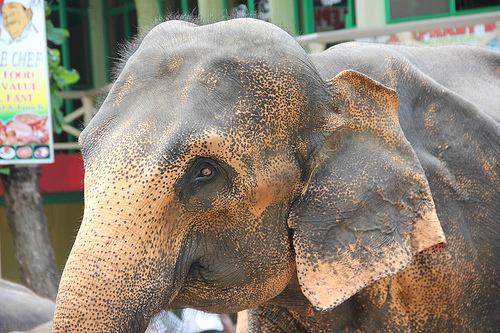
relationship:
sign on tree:
[0, 4, 57, 166] [2, 159, 64, 304]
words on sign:
[2, 38, 42, 106] [0, 4, 57, 166]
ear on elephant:
[287, 67, 448, 313] [55, 12, 498, 329]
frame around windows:
[301, 2, 317, 34] [60, 21, 457, 68]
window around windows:
[383, 0, 456, 23] [60, 21, 457, 68]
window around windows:
[91, 16, 146, 85] [60, 21, 457, 68]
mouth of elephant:
[167, 241, 232, 311] [55, 12, 498, 329]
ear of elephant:
[287, 67, 448, 313] [55, 12, 498, 329]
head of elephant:
[78, 18, 305, 306] [55, 12, 498, 329]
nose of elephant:
[48, 212, 195, 330] [55, 12, 498, 329]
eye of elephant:
[185, 158, 219, 186] [55, 12, 498, 329]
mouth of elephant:
[75, 159, 311, 331] [56, 41, 488, 289]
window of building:
[91, 16, 146, 85] [65, 15, 371, 97]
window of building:
[91, 16, 146, 85] [52, 1, 497, 51]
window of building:
[383, 0, 456, 23] [43, 0, 498, 192]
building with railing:
[5, 3, 499, 291] [44, 85, 133, 151]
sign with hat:
[0, 4, 57, 166] [3, 1, 34, 8]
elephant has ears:
[55, 12, 498, 329] [285, 68, 447, 313]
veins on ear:
[302, 183, 428, 256] [287, 67, 448, 313]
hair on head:
[90, 10, 272, 110] [51, 15, 444, 332]